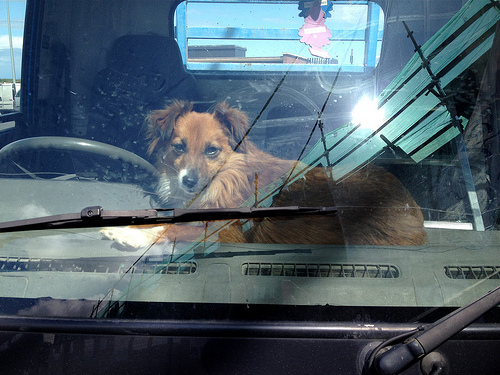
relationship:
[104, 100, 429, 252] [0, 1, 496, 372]
dog in car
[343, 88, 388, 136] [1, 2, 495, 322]
sun reflects in windscreen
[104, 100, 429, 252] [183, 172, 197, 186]
dog has nose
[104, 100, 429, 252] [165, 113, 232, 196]
dog has head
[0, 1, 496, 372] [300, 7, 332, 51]
car has air freshener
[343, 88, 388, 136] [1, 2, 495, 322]
sun reflects on windscreen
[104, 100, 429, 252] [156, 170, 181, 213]
dog has chest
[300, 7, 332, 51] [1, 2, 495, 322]
air freshener in windscreen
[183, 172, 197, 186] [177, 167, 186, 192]
nose has white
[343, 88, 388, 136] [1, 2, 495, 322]
sun shining in windscreen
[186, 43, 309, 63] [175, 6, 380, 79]
object in bed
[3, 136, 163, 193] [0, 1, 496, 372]
steering wheel on car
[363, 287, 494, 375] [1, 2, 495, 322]
whipper in front of windscreen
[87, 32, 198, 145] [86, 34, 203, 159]
seat from driver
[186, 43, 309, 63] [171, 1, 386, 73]
object in rear glass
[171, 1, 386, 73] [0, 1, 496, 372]
rear glass on car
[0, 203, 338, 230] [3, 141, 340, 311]
whipper in right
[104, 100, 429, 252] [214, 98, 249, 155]
dog has ear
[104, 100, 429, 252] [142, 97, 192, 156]
dog has ear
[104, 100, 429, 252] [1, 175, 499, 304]
dog on dashboard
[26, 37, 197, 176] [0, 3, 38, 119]
diver side has window